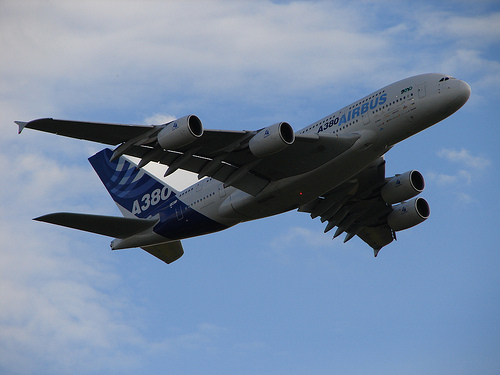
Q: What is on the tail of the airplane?
A: Numbers.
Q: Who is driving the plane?
A: Pilot.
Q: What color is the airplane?
A: White.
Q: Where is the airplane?
A: Air.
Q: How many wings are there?
A: Two.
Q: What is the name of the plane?
A: Air Bus.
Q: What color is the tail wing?
A: Blue.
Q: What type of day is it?
A: Clear.